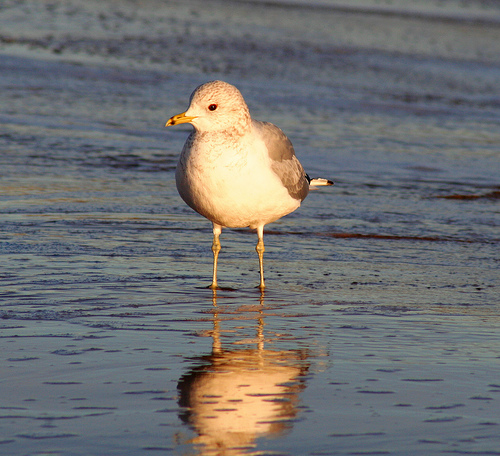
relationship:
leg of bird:
[258, 266, 267, 290] [157, 71, 345, 291]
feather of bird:
[268, 158, 286, 183] [162, 80, 331, 297]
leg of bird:
[206, 220, 226, 292] [162, 80, 331, 297]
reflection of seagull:
[179, 314, 311, 454] [161, 79, 336, 299]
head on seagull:
[162, 78, 252, 137] [161, 79, 336, 299]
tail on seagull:
[308, 170, 340, 194] [161, 79, 336, 299]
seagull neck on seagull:
[193, 126, 255, 141] [161, 79, 336, 299]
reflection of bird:
[176, 307, 312, 455] [162, 80, 335, 290]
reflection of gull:
[176, 307, 312, 455] [2, 1, 497, 451]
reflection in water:
[176, 307, 312, 455] [2, 2, 498, 453]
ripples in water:
[0, 241, 499, 453] [2, 2, 498, 453]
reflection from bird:
[176, 307, 312, 455] [150, 62, 369, 304]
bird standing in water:
[162, 80, 331, 297] [2, 2, 498, 453]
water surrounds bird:
[2, 2, 498, 453] [121, 42, 373, 349]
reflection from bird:
[176, 307, 312, 455] [162, 80, 331, 297]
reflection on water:
[176, 307, 312, 455] [2, 2, 498, 453]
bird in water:
[162, 80, 335, 290] [2, 2, 498, 453]